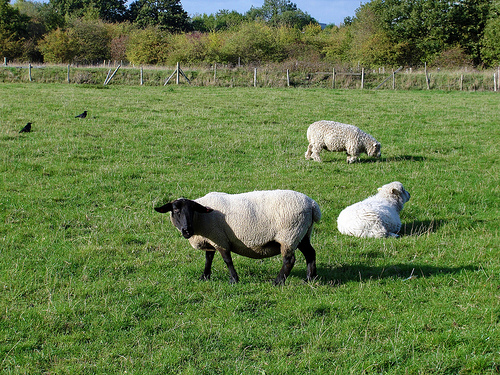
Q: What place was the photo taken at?
A: It was taken at the field.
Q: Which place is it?
A: It is a field.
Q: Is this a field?
A: Yes, it is a field.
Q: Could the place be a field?
A: Yes, it is a field.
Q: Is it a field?
A: Yes, it is a field.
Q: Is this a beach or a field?
A: It is a field.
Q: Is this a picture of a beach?
A: No, the picture is showing a field.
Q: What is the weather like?
A: It is clear.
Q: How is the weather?
A: It is clear.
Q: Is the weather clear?
A: Yes, it is clear.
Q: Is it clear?
A: Yes, it is clear.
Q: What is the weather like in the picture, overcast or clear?
A: It is clear.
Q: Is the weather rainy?
A: No, it is clear.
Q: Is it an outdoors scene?
A: Yes, it is outdoors.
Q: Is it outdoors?
A: Yes, it is outdoors.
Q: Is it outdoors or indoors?
A: It is outdoors.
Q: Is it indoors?
A: No, it is outdoors.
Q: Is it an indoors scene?
A: No, it is outdoors.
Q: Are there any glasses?
A: No, there are no glasses.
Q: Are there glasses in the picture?
A: No, there are no glasses.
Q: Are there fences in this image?
A: Yes, there is a fence.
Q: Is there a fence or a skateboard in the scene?
A: Yes, there is a fence.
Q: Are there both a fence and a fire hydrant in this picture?
A: No, there is a fence but no fire hydrants.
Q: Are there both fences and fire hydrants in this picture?
A: No, there is a fence but no fire hydrants.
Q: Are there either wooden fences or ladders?
A: Yes, there is a wood fence.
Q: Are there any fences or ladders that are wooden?
A: Yes, the fence is wooden.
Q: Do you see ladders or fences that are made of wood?
A: Yes, the fence is made of wood.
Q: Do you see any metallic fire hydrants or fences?
A: Yes, there is a metal fence.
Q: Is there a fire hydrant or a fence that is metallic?
A: Yes, the fence is metallic.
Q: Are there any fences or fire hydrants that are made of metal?
A: Yes, the fence is made of metal.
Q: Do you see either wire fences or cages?
A: Yes, there is a wire fence.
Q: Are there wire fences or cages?
A: Yes, there is a wire fence.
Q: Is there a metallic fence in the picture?
A: Yes, there is a metal fence.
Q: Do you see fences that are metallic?
A: Yes, there is a fence that is metallic.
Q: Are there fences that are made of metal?
A: Yes, there is a fence that is made of metal.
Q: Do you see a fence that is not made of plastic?
A: Yes, there is a fence that is made of metal.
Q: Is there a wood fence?
A: Yes, there is a fence that is made of wood.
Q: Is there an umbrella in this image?
A: No, there are no umbrellas.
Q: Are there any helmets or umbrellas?
A: No, there are no umbrellas or helmets.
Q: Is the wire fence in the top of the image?
A: Yes, the fence is in the top of the image.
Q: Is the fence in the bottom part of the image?
A: No, the fence is in the top of the image.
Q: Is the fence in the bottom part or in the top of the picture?
A: The fence is in the top of the image.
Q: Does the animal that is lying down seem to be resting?
A: Yes, the animal is resting.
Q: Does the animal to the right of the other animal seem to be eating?
A: No, the animal is resting.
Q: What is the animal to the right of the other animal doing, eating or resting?
A: The animal is resting.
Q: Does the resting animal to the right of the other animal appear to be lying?
A: Yes, the animal is lying.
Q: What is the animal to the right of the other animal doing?
A: The animal is lying.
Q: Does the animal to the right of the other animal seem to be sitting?
A: No, the animal is lying.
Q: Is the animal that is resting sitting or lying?
A: The animal is lying.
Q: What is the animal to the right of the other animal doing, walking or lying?
A: The animal is lying.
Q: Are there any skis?
A: No, there are no skis.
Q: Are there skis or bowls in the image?
A: No, there are no skis or bowls.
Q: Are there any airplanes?
A: No, there are no airplanes.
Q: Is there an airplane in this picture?
A: No, there are no airplanes.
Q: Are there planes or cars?
A: No, there are no planes or cars.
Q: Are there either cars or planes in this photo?
A: No, there are no planes or cars.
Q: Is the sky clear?
A: Yes, the sky is clear.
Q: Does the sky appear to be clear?
A: Yes, the sky is clear.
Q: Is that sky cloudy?
A: No, the sky is clear.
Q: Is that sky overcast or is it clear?
A: The sky is clear.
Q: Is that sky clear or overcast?
A: The sky is clear.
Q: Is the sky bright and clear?
A: Yes, the sky is bright and clear.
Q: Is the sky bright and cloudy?
A: No, the sky is bright but clear.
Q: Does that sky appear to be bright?
A: Yes, the sky is bright.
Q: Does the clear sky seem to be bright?
A: Yes, the sky is bright.